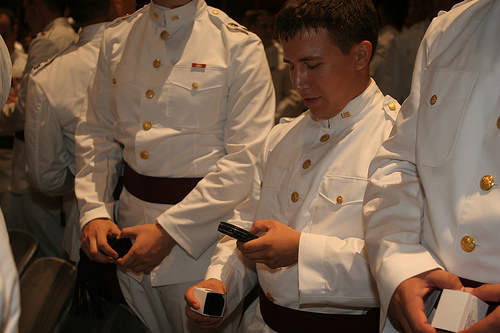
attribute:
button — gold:
[458, 234, 478, 253]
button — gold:
[317, 131, 330, 142]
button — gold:
[300, 157, 310, 170]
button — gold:
[289, 188, 299, 204]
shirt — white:
[202, 78, 402, 329]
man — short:
[182, 1, 401, 328]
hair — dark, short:
[273, 0, 380, 64]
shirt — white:
[360, 14, 482, 331]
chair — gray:
[6, 226, 40, 279]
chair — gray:
[17, 252, 79, 331]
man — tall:
[72, 1, 276, 331]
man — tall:
[360, 0, 485, 330]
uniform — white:
[21, 21, 114, 264]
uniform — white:
[71, 0, 274, 330]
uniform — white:
[202, 79, 400, 330]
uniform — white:
[359, 1, 481, 331]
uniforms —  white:
[185, 159, 455, 192]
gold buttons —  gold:
[283, 150, 332, 209]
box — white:
[432, 294, 463, 333]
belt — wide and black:
[128, 132, 204, 253]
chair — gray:
[14, 234, 144, 333]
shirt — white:
[74, 54, 181, 217]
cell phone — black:
[212, 217, 258, 257]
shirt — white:
[74, 136, 224, 324]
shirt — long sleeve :
[80, 55, 260, 269]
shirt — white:
[32, 116, 200, 310]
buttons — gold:
[142, 118, 160, 163]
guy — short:
[178, 3, 411, 331]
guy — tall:
[72, 1, 277, 331]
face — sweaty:
[277, 25, 362, 122]